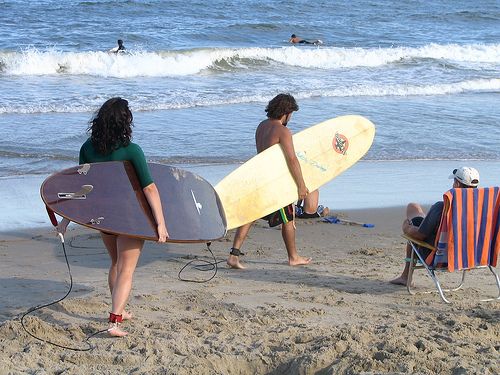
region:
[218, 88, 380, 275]
man holding white surfboard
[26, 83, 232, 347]
woman holding brown surfboard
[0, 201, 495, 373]
sand on beach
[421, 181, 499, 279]
red and blue striped towel on back of chair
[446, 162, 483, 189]
baseball cap on person in folding chair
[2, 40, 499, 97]
white waves in water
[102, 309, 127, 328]
red surfboard tether cuff on woman's ankle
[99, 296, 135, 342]
a cuff around a leg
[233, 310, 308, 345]
sand at the beach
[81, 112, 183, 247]
a woman with a surf board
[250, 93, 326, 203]
a mna with a surf board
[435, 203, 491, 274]
a orange and blue towel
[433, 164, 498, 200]
a man wearing a hat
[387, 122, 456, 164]
water at the beach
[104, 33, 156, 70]
a man in the water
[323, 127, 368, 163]
a symbol on the surf board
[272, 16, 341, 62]
a man surfing at the beach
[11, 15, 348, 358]
surfers on the beach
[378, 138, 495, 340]
person in lawn chair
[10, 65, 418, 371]
surfers in the water riding the wave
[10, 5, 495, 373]
a scene outside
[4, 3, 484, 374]
a scene at the beach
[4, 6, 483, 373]
an image during the day time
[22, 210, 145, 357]
ankle bracelet attached to surfboard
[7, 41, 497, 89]
a huge wave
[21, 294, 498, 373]
kicked up sand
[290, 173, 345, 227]
a person sitting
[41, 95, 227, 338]
Woman walking on beach with a surfboard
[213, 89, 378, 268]
Man walking on the beach with a surfboard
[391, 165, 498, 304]
Man sitting on a beach chair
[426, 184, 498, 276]
Striped towel hanging over back of beach chair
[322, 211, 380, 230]
Shovel in the sand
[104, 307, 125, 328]
Leash on woman's ankle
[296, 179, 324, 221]
Man sitting in the sand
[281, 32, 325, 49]
Person lying on surfboard in the water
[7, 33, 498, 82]
Wave crashing in the water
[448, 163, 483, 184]
White cap on man's head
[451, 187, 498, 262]
a red and blue striped towel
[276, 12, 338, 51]
a man lying on a surfboad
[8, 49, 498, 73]
white breaking waves in the ocean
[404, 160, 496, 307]
man siting in a beach chair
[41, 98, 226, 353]
woman wearing a green shirt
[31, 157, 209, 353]
surf board attached to the ankle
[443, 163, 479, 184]
man wearing a white cap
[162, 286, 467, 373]
footprints in the sandy beach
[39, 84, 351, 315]
a man and a woman carrying surf boards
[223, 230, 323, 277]
a man is walking barefoot in the sand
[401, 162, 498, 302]
A person sitting in a beach chair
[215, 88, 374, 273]
man holding a white surfboards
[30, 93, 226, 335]
a woman holding a blue surfboard